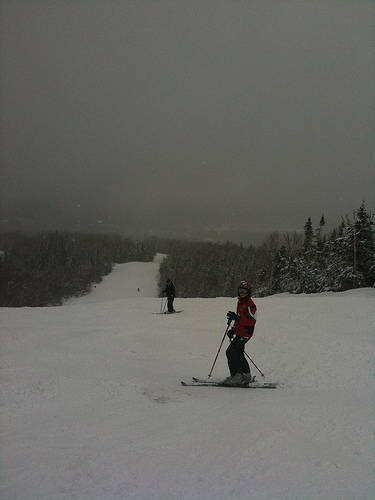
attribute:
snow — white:
[68, 332, 137, 419]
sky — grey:
[186, 16, 265, 115]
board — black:
[195, 375, 237, 397]